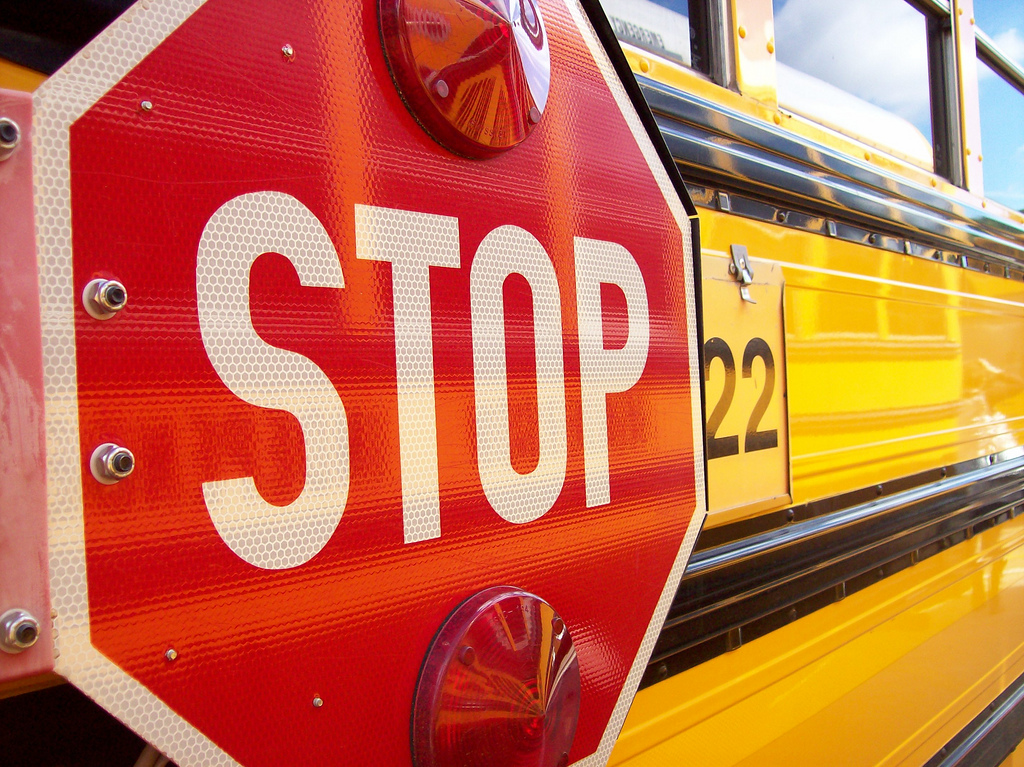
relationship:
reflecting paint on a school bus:
[28, 0, 709, 767] [665, 44, 992, 697]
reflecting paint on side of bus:
[28, 0, 709, 767] [0, 0, 1024, 767]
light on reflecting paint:
[410, 585, 582, 767] [28, 0, 709, 767]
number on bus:
[704, 337, 778, 460] [0, 0, 1024, 767]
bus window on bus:
[599, 0, 711, 76] [0, 0, 1024, 767]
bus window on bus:
[774, 0, 954, 181] [0, 0, 1024, 767]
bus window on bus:
[974, 34, 1023, 217] [0, 0, 1024, 767]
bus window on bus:
[774, 0, 954, 181] [122, 7, 907, 626]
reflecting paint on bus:
[28, 0, 709, 767] [42, 29, 985, 734]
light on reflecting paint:
[397, 571, 594, 742] [28, 0, 709, 767]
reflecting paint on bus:
[28, 0, 709, 767] [69, 46, 1018, 721]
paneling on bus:
[665, 68, 1018, 244] [553, 67, 1022, 698]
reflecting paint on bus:
[28, 0, 709, 767] [470, 63, 989, 759]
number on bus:
[648, 286, 860, 570] [166, 57, 990, 604]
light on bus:
[410, 585, 582, 767] [397, 41, 938, 614]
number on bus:
[704, 337, 778, 460] [203, 44, 1012, 731]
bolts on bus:
[82, 278, 136, 485] [159, 18, 1013, 759]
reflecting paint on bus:
[28, 0, 709, 767] [203, 44, 1012, 731]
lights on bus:
[375, 0, 580, 767] [421, 52, 1018, 737]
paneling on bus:
[632, 76, 1024, 270] [578, 52, 1000, 722]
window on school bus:
[592, 0, 1021, 218] [498, 113, 1019, 682]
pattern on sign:
[216, 197, 331, 286] [71, 74, 733, 671]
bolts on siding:
[673, 158, 782, 331] [639, 102, 1022, 258]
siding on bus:
[639, 102, 1022, 258] [447, 28, 999, 728]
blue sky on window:
[647, 0, 1024, 218] [592, 0, 1021, 218]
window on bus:
[592, 0, 1021, 218] [622, 28, 1022, 605]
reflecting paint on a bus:
[28, 0, 709, 767] [739, 20, 949, 742]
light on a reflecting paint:
[410, 585, 582, 767] [28, 0, 709, 767]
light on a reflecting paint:
[392, 14, 565, 153] [28, 0, 709, 767]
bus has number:
[0, 0, 1024, 767] [704, 337, 778, 460]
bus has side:
[0, 0, 1024, 767] [707, 17, 989, 756]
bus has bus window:
[0, 0, 1024, 767] [774, 0, 954, 181]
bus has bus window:
[0, 0, 1024, 767] [599, 0, 711, 76]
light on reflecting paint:
[377, 1, 550, 161] [28, 0, 709, 767]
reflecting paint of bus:
[28, 0, 709, 767] [0, 0, 1024, 767]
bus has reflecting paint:
[0, 0, 1024, 767] [28, 0, 709, 767]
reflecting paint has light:
[28, 0, 709, 767] [377, 1, 550, 161]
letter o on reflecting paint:
[469, 228, 563, 525] [28, 0, 709, 767]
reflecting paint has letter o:
[28, 0, 709, 767] [469, 228, 563, 525]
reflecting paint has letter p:
[28, 0, 709, 767] [575, 222, 655, 506]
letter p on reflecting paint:
[575, 222, 655, 506] [28, 0, 709, 767]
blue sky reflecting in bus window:
[889, 94, 931, 149] [774, 0, 954, 181]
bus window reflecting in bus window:
[774, 0, 954, 181] [774, 0, 954, 181]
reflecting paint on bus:
[28, 0, 709, 767] [0, 0, 1024, 767]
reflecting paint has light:
[28, 0, 709, 767] [410, 585, 582, 767]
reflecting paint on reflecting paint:
[94, 570, 429, 664] [28, 0, 709, 767]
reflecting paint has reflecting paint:
[28, 0, 709, 767] [94, 570, 429, 664]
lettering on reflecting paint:
[195, 191, 649, 570] [28, 0, 709, 767]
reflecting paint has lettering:
[28, 0, 709, 767] [195, 191, 649, 570]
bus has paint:
[0, 0, 1024, 767] [767, 455, 973, 685]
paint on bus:
[767, 455, 973, 685] [0, 0, 1024, 767]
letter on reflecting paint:
[195, 191, 348, 571] [28, 0, 709, 767]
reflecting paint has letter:
[28, 0, 709, 767] [195, 191, 348, 571]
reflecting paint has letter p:
[28, 0, 709, 767] [573, 236, 650, 509]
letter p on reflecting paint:
[573, 236, 650, 509] [28, 0, 709, 767]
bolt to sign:
[78, 269, 126, 324] [24, 1, 709, 758]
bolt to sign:
[89, 440, 137, 488] [24, 1, 709, 758]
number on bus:
[704, 337, 778, 460] [42, 29, 985, 734]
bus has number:
[42, 29, 985, 734] [704, 337, 778, 460]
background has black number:
[687, 244, 791, 526] [696, 338, 735, 464]